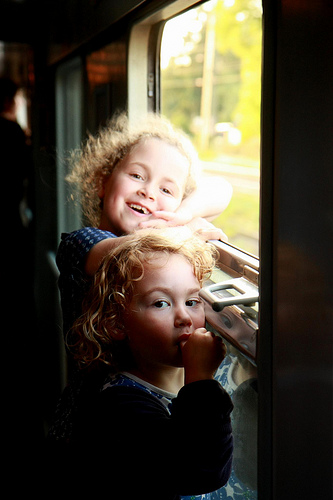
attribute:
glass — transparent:
[160, 2, 260, 259]